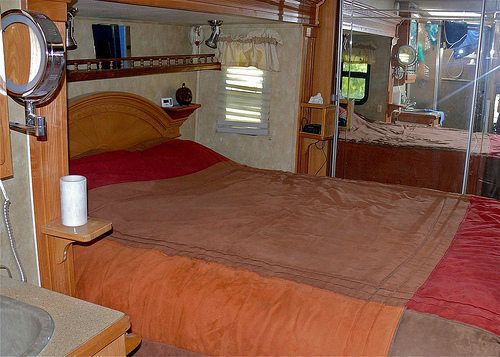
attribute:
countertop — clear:
[1, 268, 123, 352]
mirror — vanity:
[333, 10, 499, 176]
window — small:
[216, 53, 271, 135]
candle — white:
[62, 170, 83, 225]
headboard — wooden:
[69, 98, 186, 153]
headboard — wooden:
[72, 29, 179, 151]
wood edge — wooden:
[1, 272, 126, 355]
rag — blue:
[423, 106, 446, 126]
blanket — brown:
[64, 134, 498, 355]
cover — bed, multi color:
[71, 140, 498, 353]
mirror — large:
[331, 2, 492, 171]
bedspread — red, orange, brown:
[73, 137, 498, 354]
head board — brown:
[69, 90, 183, 150]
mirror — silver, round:
[9, 9, 71, 109]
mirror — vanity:
[349, 30, 462, 186]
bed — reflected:
[340, 103, 498, 185]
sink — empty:
[3, 276, 138, 355]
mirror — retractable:
[1, 2, 66, 149]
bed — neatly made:
[59, 93, 482, 355]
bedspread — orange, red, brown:
[82, 114, 344, 340]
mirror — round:
[3, 17, 60, 152]